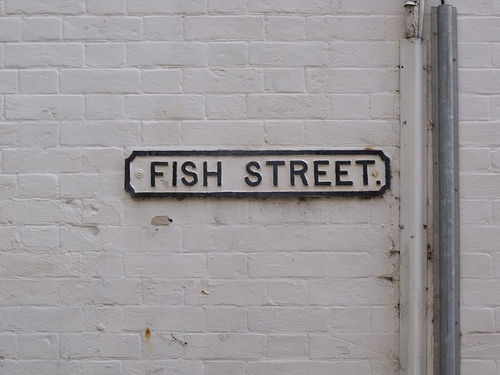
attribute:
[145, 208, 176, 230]
peeling paint — peeling 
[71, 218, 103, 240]
peeling paint — peeling 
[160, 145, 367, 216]
sign — white , black 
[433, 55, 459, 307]
pipe — grey 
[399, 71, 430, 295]
pipe — white 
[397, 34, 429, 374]
protector — wire , painted white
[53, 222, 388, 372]
bricked wall — brick, white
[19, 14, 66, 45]
brick — white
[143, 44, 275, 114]
wall — brick, white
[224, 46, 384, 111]
wall — bricked, white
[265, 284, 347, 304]
brick — white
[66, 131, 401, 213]
sign — rectangular , long 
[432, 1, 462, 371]
pipe — metal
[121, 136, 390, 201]
black border — black 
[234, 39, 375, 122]
wall — painted 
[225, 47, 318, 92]
wall — painted, white, brick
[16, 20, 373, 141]
wall — painted 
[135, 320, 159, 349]
spot — rusty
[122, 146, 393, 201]
border — black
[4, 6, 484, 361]
wall — white, bricked, brick, painted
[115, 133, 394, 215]
sign — white